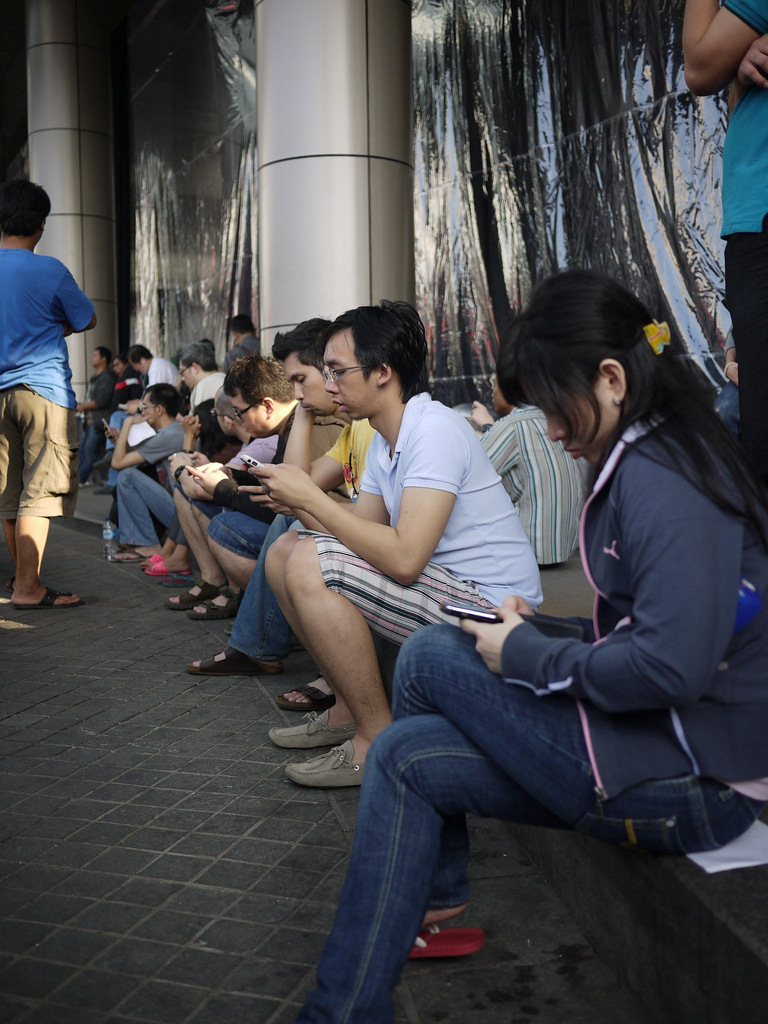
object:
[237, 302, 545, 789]
man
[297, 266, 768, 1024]
woman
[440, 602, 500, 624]
cellphone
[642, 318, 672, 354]
hairclip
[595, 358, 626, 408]
ear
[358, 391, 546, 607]
shirt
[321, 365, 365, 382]
glasses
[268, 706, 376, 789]
brown shoes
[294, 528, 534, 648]
shorts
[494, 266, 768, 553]
black hair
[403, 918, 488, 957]
flip flop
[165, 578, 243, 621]
sandals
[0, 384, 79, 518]
shorts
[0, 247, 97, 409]
shirt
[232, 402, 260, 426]
glasses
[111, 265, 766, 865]
sitting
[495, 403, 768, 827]
jacket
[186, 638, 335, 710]
sandals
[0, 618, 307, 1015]
tiles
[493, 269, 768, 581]
long hair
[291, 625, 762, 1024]
blue jeans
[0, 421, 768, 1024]
tiles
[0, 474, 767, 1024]
ground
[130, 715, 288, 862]
ground